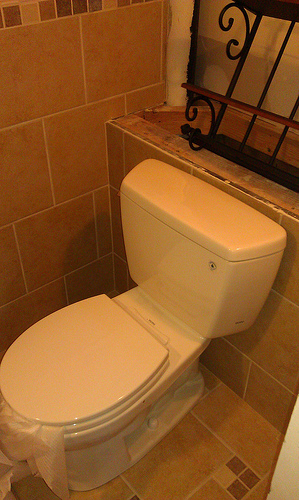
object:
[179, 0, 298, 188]
rack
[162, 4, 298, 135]
wall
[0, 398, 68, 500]
paper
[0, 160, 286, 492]
toilet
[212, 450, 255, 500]
tiles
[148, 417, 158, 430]
bolt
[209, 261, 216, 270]
logo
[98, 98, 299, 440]
drywall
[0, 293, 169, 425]
lid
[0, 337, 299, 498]
floor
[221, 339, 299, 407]
lines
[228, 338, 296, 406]
grout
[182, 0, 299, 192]
rail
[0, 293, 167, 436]
seat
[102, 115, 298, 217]
rock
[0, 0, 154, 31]
tile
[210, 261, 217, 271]
name